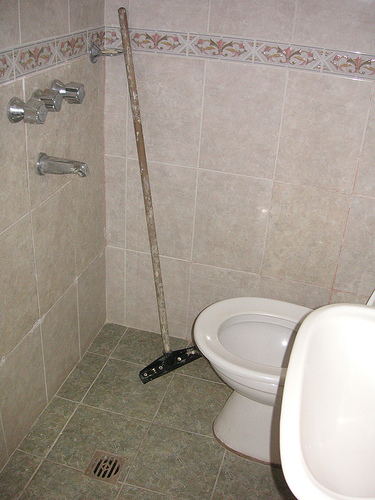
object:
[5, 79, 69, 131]
shower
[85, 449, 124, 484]
drain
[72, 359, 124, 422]
tile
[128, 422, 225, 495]
tile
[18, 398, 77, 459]
tile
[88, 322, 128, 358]
tile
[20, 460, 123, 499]
tile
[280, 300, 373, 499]
sink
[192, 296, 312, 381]
toilet seat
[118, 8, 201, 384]
paint scraper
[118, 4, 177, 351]
handle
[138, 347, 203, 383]
bottom piece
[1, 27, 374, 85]
tile lining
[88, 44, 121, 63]
towel rack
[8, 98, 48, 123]
temperature knob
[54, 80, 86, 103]
temperature knob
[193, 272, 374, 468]
toilet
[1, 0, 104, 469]
wall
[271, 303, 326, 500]
shadow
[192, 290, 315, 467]
toilet bowl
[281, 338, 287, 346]
glare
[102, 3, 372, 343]
wall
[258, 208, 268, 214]
glare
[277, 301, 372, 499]
lip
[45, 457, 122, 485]
grout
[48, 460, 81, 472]
red stain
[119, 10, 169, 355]
paint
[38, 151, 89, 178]
faucet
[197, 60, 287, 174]
tile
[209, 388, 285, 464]
toilet base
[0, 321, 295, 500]
floor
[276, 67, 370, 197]
tile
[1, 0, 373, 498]
bathroom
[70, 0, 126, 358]
corner tiles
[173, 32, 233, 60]
pattern